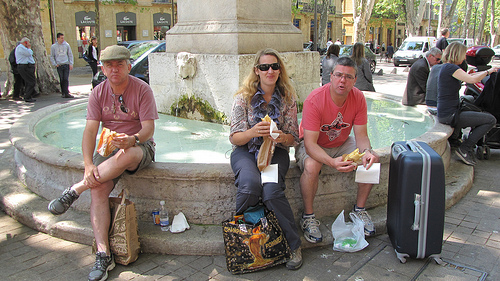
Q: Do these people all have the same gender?
A: No, they are both male and female.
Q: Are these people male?
A: No, they are both male and female.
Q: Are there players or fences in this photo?
A: No, there are no fences or players.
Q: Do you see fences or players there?
A: No, there are no fences or players.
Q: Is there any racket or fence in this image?
A: No, there are no fences or rackets.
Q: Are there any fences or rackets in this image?
A: No, there are no fences or rackets.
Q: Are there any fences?
A: No, there are no fences.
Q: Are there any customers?
A: No, there are no customers.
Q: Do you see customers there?
A: No, there are no customers.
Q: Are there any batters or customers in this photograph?
A: No, there are no customers or batters.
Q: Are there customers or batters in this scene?
A: No, there are no customers or batters.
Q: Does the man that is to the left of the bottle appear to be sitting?
A: Yes, the man is sitting.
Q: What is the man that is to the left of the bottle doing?
A: The man is sitting.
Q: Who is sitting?
A: The man is sitting.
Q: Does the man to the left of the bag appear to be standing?
A: No, the man is sitting.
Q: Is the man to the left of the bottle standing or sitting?
A: The man is sitting.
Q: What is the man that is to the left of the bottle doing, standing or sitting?
A: The man is sitting.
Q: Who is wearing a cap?
A: The man is wearing a cap.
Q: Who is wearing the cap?
A: The man is wearing a cap.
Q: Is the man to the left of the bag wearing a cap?
A: Yes, the man is wearing a cap.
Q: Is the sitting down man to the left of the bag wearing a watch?
A: No, the man is wearing a cap.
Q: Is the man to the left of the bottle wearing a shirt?
A: Yes, the man is wearing a shirt.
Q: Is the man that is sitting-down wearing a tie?
A: No, the man is wearing a shirt.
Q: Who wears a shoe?
A: The man wears a shoe.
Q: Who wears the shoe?
A: The man wears a shoe.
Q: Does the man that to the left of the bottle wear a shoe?
A: Yes, the man wears a shoe.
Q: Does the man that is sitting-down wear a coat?
A: No, the man wears a shoe.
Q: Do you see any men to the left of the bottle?
A: Yes, there is a man to the left of the bottle.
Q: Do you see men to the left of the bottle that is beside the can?
A: Yes, there is a man to the left of the bottle.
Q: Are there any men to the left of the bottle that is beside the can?
A: Yes, there is a man to the left of the bottle.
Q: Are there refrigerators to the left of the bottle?
A: No, there is a man to the left of the bottle.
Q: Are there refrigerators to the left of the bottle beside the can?
A: No, there is a man to the left of the bottle.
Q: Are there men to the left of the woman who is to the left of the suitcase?
A: Yes, there is a man to the left of the woman.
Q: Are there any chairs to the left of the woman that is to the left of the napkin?
A: No, there is a man to the left of the woman.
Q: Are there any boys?
A: No, there are no boys.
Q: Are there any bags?
A: Yes, there is a bag.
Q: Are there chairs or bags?
A: Yes, there is a bag.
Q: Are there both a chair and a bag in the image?
A: No, there is a bag but no chairs.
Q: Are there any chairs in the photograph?
A: No, there are no chairs.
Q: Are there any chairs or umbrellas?
A: No, there are no chairs or umbrellas.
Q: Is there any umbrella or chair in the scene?
A: No, there are no chairs or umbrellas.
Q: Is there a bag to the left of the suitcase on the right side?
A: Yes, there is a bag to the left of the suitcase.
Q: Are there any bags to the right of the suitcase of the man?
A: No, the bag is to the left of the suitcase.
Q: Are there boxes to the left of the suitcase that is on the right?
A: No, there is a bag to the left of the suitcase.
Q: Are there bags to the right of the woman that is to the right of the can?
A: Yes, there is a bag to the right of the woman.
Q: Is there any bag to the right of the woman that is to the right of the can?
A: Yes, there is a bag to the right of the woman.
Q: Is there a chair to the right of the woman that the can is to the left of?
A: No, there is a bag to the right of the woman.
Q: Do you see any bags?
A: Yes, there is a bag.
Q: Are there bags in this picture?
A: Yes, there is a bag.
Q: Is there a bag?
A: Yes, there is a bag.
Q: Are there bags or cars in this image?
A: Yes, there is a bag.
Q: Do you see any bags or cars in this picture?
A: Yes, there is a bag.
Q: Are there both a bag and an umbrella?
A: No, there is a bag but no umbrellas.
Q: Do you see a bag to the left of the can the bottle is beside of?
A: Yes, there is a bag to the left of the can.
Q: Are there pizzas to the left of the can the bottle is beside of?
A: No, there is a bag to the left of the can.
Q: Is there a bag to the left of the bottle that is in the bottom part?
A: Yes, there is a bag to the left of the bottle.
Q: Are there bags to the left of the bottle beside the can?
A: Yes, there is a bag to the left of the bottle.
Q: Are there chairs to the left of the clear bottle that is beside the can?
A: No, there is a bag to the left of the bottle.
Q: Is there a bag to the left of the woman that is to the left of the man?
A: Yes, there is a bag to the left of the woman.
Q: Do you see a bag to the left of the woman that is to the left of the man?
A: Yes, there is a bag to the left of the woman.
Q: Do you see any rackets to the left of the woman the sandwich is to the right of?
A: No, there is a bag to the left of the woman.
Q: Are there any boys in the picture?
A: No, there are no boys.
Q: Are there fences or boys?
A: No, there are no boys or fences.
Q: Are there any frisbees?
A: No, there are no frisbees.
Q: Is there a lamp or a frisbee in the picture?
A: No, there are no frisbees or lamps.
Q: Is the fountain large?
A: Yes, the fountain is large.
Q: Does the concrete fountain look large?
A: Yes, the fountain is large.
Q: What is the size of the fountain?
A: The fountain is large.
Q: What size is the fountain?
A: The fountain is large.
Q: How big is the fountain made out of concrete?
A: The fountain is large.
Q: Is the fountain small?
A: No, the fountain is large.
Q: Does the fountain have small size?
A: No, the fountain is large.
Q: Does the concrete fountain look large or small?
A: The fountain is large.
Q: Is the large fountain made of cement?
A: Yes, the fountain is made of cement.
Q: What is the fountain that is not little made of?
A: The fountain is made of concrete.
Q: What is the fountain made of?
A: The fountain is made of concrete.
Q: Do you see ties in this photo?
A: No, there are no ties.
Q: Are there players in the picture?
A: No, there are no players.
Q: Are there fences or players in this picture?
A: No, there are no players or fences.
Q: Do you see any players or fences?
A: No, there are no players or fences.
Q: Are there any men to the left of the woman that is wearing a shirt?
A: Yes, there is a man to the left of the woman.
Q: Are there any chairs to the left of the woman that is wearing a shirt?
A: No, there is a man to the left of the woman.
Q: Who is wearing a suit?
A: The man is wearing a suit.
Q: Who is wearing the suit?
A: The man is wearing a suit.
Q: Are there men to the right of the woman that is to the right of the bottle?
A: Yes, there is a man to the right of the woman.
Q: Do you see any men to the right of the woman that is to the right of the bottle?
A: Yes, there is a man to the right of the woman.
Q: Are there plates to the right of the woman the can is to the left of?
A: No, there is a man to the right of the woman.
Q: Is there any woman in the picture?
A: Yes, there is a woman.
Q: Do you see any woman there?
A: Yes, there is a woman.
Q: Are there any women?
A: Yes, there is a woman.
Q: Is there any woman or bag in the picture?
A: Yes, there is a woman.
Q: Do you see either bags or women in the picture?
A: Yes, there is a woman.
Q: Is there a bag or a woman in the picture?
A: Yes, there is a woman.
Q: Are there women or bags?
A: Yes, there is a woman.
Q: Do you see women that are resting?
A: Yes, there is a woman that is resting.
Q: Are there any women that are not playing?
A: Yes, there is a woman that is resting.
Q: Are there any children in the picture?
A: No, there are no children.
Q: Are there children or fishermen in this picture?
A: No, there are no children or fishermen.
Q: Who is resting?
A: The woman is resting.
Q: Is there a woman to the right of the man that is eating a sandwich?
A: Yes, there is a woman to the right of the man.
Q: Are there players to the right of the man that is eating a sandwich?
A: No, there is a woman to the right of the man.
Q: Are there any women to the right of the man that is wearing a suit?
A: Yes, there is a woman to the right of the man.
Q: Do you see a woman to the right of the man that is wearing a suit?
A: Yes, there is a woman to the right of the man.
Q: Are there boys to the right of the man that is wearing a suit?
A: No, there is a woman to the right of the man.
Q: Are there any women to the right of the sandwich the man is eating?
A: Yes, there is a woman to the right of the sandwich.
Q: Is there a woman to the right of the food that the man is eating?
A: Yes, there is a woman to the right of the sandwich.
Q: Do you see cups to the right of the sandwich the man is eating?
A: No, there is a woman to the right of the sandwich.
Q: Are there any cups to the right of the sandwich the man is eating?
A: No, there is a woman to the right of the sandwich.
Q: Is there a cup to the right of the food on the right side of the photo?
A: No, there is a woman to the right of the sandwich.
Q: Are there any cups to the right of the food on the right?
A: No, there is a woman to the right of the sandwich.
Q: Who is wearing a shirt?
A: The woman is wearing a shirt.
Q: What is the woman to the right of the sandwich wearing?
A: The woman is wearing a shirt.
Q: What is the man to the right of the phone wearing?
A: The man is wearing a shirt.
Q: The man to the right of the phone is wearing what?
A: The man is wearing a shirt.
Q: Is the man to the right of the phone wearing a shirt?
A: Yes, the man is wearing a shirt.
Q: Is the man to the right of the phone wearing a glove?
A: No, the man is wearing a shirt.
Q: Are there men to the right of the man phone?
A: Yes, there is a man to the right of the phone.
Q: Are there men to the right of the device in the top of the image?
A: Yes, there is a man to the right of the phone.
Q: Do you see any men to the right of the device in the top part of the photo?
A: Yes, there is a man to the right of the phone.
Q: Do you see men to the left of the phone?
A: No, the man is to the right of the phone.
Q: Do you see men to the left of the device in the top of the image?
A: No, the man is to the right of the phone.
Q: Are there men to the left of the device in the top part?
A: No, the man is to the right of the phone.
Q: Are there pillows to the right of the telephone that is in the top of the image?
A: No, there is a man to the right of the telephone.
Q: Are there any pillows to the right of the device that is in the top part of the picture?
A: No, there is a man to the right of the telephone.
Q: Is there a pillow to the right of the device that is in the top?
A: No, there is a man to the right of the telephone.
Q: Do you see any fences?
A: No, there are no fences.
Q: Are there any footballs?
A: No, there are no footballs.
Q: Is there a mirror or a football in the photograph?
A: No, there are no footballs or mirrors.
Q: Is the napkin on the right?
A: Yes, the napkin is on the right of the image.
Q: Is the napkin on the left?
A: No, the napkin is on the right of the image.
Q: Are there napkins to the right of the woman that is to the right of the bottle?
A: Yes, there is a napkin to the right of the woman.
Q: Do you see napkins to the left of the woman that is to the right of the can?
A: No, the napkin is to the right of the woman.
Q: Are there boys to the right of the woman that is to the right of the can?
A: No, there is a napkin to the right of the woman.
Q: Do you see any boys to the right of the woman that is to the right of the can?
A: No, there is a napkin to the right of the woman.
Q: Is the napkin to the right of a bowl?
A: No, the napkin is to the right of a woman.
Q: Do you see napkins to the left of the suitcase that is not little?
A: Yes, there is a napkin to the left of the suitcase.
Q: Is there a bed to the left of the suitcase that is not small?
A: No, there is a napkin to the left of the suitcase.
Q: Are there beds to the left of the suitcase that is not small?
A: No, there is a napkin to the left of the suitcase.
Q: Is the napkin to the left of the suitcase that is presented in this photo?
A: Yes, the napkin is to the left of the suitcase.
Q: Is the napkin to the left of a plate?
A: No, the napkin is to the left of the suitcase.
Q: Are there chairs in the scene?
A: No, there are no chairs.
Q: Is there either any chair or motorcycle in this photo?
A: No, there are no chairs or motorcycles.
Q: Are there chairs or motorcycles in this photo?
A: No, there are no chairs or motorcycles.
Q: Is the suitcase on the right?
A: Yes, the suitcase is on the right of the image.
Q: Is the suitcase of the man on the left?
A: No, the suitcase is on the right of the image.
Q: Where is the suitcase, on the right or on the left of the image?
A: The suitcase is on the right of the image.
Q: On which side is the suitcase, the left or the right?
A: The suitcase is on the right of the image.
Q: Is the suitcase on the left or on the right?
A: The suitcase is on the right of the image.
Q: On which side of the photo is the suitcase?
A: The suitcase is on the right of the image.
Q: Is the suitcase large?
A: Yes, the suitcase is large.